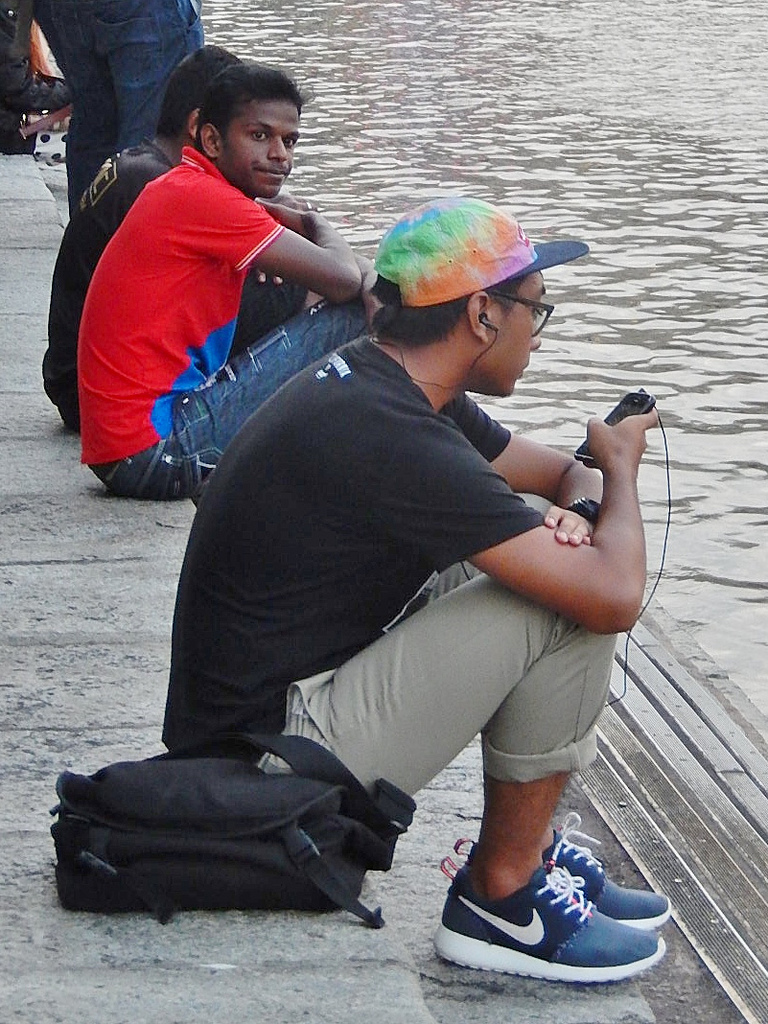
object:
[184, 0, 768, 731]
water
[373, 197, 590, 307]
cap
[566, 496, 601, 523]
watch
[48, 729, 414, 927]
bag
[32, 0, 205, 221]
person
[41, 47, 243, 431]
person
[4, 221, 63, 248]
stone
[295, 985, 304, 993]
stone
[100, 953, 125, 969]
stone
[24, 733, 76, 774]
stone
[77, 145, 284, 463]
shirt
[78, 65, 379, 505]
boy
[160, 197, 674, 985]
boy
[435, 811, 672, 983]
pair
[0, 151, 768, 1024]
floor